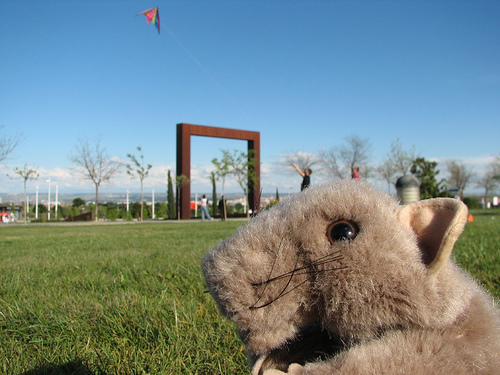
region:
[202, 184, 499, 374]
A light brown stuffed mouse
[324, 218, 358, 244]
The black and brown eye of a little stuffed animal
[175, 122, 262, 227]
Very large brown wooden frame in the background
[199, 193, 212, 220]
A person in a white shirt and light colored jeans by a large frame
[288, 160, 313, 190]
A man in a black shirt with his arms up.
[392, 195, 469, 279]
Small tan colored ear of a stuffed animal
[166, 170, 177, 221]
Tall thin pine tree next to a large brown frame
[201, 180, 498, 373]
A light brown mouse with a brown and black eye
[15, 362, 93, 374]
Shadow cast on the grass by the mouse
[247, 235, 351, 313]
Black whiskers on a mouses face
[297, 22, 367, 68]
blue sky above the land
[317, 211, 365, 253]
eye of the animal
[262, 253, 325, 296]
whiskers on the animal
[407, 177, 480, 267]
ear of the animal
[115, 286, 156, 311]
grass on the ground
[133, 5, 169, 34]
kite above the ground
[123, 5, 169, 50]
different colored kite in the air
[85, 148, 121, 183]
tree in the background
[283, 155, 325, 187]
man flying the kite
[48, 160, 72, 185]
cloud in the sky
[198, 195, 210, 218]
A person near the field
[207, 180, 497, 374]
A stuffed animal on the grass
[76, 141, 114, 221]
A bare tree in the distance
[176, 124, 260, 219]
A square desig above the field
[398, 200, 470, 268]
The ear of the stuffed animal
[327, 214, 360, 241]
A beady eye on the stuffed animal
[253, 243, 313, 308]
Whiskers on the stuffed animal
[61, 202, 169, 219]
Green trees behind the bare trees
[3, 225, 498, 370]
An empty green field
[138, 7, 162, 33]
A kite in the sky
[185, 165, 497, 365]
a plush color gray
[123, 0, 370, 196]
people flying a kite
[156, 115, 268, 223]
an arch of wood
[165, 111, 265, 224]
two people under an arch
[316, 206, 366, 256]
a black and brown eye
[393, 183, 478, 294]
a brown ear of plush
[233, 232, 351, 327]
whiskers of plush are black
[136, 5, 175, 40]
a kite color red, green and blue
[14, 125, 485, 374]
a field covered with green grass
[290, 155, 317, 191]
man wears a black top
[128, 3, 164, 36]
Kite flying in the sky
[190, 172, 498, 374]
Stuffed toy mouse on the ground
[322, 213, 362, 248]
Plastic brown and black eye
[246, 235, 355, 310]
Plastic whiskers that are disheveled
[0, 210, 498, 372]
Field of green grass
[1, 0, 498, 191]
Blue sky with a few clouds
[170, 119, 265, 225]
Structure for cars to drive under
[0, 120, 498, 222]
Trees with and without leaves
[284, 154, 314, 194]
Person with arms outstreched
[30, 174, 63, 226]
Lamp posts to provide light